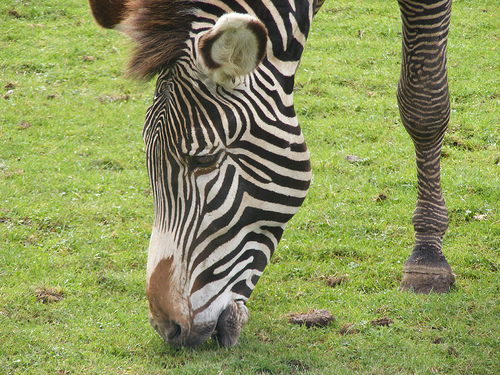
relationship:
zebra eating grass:
[85, 1, 461, 353] [145, 343, 253, 372]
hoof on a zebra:
[398, 247, 456, 296] [85, 1, 461, 353]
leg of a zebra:
[391, 0, 458, 295] [85, 1, 461, 353]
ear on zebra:
[199, 13, 270, 90] [85, 1, 461, 353]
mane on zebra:
[121, 0, 197, 84] [85, 1, 461, 353]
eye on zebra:
[181, 145, 229, 181] [85, 1, 461, 353]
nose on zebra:
[145, 312, 196, 344] [85, 1, 461, 353]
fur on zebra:
[250, 107, 279, 136] [85, 1, 461, 353]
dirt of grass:
[290, 310, 331, 326] [273, 269, 366, 345]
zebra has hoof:
[85, 1, 461, 353] [398, 247, 456, 296]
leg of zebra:
[391, 0, 458, 295] [85, 1, 461, 353]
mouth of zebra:
[201, 304, 239, 347] [85, 1, 461, 353]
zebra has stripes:
[85, 1, 461, 353] [198, 200, 269, 251]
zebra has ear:
[85, 1, 461, 353] [199, 13, 270, 90]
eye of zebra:
[181, 145, 229, 181] [85, 1, 461, 353]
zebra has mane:
[85, 1, 461, 353] [121, 0, 197, 84]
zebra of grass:
[85, 1, 461, 353] [273, 269, 366, 345]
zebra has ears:
[85, 1, 461, 353] [90, 2, 268, 79]